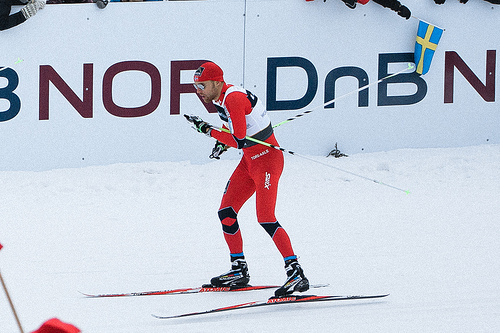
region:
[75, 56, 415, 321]
the skier is on the snow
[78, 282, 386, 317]
the skier is on two skis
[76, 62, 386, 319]
the uniform is red and white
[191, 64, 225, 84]
the man has a red cap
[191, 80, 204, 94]
the man is wearing glasses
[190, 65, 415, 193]
the man is holding two sticks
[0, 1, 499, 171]
the wall has letters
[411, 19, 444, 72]
the flag is yellow and blue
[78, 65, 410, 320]
the man is skiing for sport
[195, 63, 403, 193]
the sticks are white and black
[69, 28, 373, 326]
a man on skis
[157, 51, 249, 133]
he is wearing a red hat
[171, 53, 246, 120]
he is wearing goggles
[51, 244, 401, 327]
the skis are red and white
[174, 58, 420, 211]
the ski poles are black and white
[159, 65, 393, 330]
the man is wearing red and white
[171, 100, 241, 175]
he is wearing gloves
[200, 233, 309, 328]
his ski boots are black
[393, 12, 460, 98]
a blue and yellow flag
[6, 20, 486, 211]
a sign is behind the man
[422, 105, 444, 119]
part of a board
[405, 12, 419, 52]
edge of a flag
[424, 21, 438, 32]
handle of a flag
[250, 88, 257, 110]
back of a man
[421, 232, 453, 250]
part of a surface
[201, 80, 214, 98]
face of a man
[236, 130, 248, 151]
elbow of a man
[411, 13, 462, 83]
the flag is blue with a yellow cross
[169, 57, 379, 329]
the skier is wearing a red black and white outfit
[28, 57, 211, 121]
the word in the background is maroon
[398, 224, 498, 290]
the snow is white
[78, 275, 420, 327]
the ski's are red and white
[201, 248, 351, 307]
the skiers boots are black white blue and red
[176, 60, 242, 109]
the skier is wearing sunglasses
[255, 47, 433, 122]
the word on the background is blue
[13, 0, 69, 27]
the person in the crowd is wearing a white glove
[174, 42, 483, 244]
the skiers poles are white and black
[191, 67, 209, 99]
a skier with sun glasses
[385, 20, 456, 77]
a swedish flag being pulled from skier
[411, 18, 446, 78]
blue and yellow flag flying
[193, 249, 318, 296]
a skier with two black ski boots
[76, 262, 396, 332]
two red and silver skis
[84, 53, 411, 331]
a skier in a red snowsuit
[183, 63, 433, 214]
two ski poles skier is carrying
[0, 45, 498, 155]
a name of event in black on back gate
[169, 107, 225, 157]
a skier wearing black gloves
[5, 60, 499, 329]
skier is skiing on snow